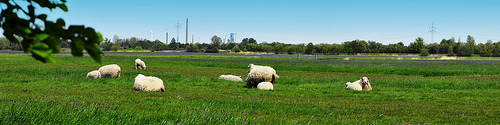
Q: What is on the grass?
A: Sheep.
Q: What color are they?
A: White.